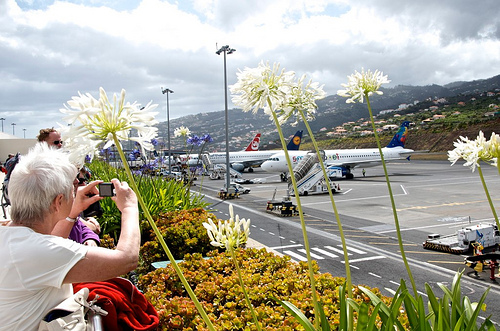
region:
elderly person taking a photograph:
[7, 142, 142, 311]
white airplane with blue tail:
[275, 118, 413, 183]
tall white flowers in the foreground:
[60, 60, 493, 325]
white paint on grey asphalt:
[195, 190, 491, 325]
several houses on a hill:
[321, 85, 491, 150]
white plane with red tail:
[165, 130, 262, 173]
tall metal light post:
[213, 42, 238, 202]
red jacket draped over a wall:
[71, 275, 159, 329]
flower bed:
[83, 161, 428, 327]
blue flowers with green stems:
[86, 124, 214, 205]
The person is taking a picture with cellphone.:
[6, 155, 147, 307]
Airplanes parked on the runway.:
[174, 135, 410, 214]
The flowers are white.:
[229, 66, 403, 109]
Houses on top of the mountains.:
[162, 102, 459, 147]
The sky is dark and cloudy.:
[102, 17, 377, 89]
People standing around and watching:
[22, 118, 89, 318]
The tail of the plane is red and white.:
[240, 125, 265, 152]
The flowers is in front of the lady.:
[168, 231, 328, 329]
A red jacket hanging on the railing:
[91, 275, 146, 323]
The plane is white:
[276, 145, 428, 184]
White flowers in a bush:
[226, 53, 463, 325]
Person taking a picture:
[5, 135, 152, 300]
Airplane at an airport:
[267, 111, 440, 203]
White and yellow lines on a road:
[306, 202, 386, 288]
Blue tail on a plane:
[384, 114, 412, 160]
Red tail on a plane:
[237, 121, 265, 151]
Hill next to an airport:
[182, 82, 467, 186]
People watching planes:
[14, 118, 159, 312]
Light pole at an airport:
[153, 78, 198, 186]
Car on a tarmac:
[218, 174, 256, 194]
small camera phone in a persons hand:
[97, 181, 116, 196]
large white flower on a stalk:
[227, 61, 294, 115]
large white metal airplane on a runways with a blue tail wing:
[261, 122, 428, 176]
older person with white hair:
[0, 145, 142, 330]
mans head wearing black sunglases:
[37, 128, 64, 147]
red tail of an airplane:
[245, 134, 262, 151]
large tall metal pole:
[216, 45, 233, 196]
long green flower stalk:
[365, 94, 419, 301]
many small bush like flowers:
[137, 250, 404, 328]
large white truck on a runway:
[421, 221, 498, 250]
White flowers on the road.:
[224, 48, 400, 168]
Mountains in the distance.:
[176, 82, 360, 167]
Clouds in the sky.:
[313, 14, 432, 156]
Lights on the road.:
[106, 26, 291, 214]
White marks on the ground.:
[261, 202, 423, 301]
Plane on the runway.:
[239, 117, 479, 221]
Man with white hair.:
[21, 135, 218, 324]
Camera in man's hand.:
[78, 136, 213, 260]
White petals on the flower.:
[55, 77, 294, 244]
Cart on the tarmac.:
[256, 186, 316, 221]